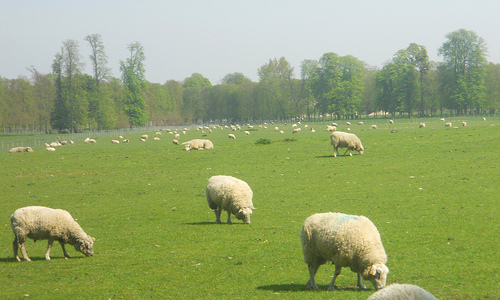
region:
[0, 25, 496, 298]
a large green field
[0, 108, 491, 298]
a field of white sheep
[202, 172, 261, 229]
a sheep bent forwards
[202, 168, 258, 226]
a white sheep eating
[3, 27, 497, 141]
a row of green trees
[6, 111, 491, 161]
many small sheep in the background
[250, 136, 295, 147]
a small bush in the field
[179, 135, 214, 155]
some rocks in the field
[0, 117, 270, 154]
a light grey fence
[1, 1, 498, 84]
a grey sky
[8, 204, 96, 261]
a white sheep grazing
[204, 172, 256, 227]
a white sheep grazing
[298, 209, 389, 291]
a white sheep grazing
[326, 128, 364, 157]
a white sheep grazing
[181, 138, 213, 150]
a white sheep grazing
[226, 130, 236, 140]
a white sheep grazing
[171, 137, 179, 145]
a white sheep grazing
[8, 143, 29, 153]
a white sheep grazing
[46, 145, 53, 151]
a white sheep grazing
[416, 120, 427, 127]
a white sheep grazing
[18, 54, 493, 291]
sheep in a field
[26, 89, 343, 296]
white sheep in a field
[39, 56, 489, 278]
sheep eatting green grass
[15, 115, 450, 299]
white sheep eatting grass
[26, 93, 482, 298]
white sheep eatting a green grass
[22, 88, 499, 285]
a field of sheep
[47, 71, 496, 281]
an area with sheep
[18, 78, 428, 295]
an area of white sheep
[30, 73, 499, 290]
sheep all in a field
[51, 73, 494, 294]
a green grass field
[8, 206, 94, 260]
sheep in the field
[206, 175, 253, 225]
sheep in the field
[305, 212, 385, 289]
sheep in the field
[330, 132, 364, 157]
sheep in the field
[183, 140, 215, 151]
sheep in the field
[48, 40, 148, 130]
group of green trees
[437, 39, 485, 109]
green trees in field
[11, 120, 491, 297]
green grass under sheep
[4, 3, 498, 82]
grey sky above tree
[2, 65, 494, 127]
large group of trees behind sheep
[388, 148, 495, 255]
lush green grass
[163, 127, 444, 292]
several sheep eating grass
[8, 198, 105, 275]
a sheep eating grass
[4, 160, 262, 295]
two sheep eating grass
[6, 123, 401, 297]
four sheep eating grass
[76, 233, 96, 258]
the head of a sheep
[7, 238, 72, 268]
the legs of a sheep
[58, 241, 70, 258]
the front leg of a sheep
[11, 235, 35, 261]
the back legs of a sheep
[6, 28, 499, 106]
several trees in a forest